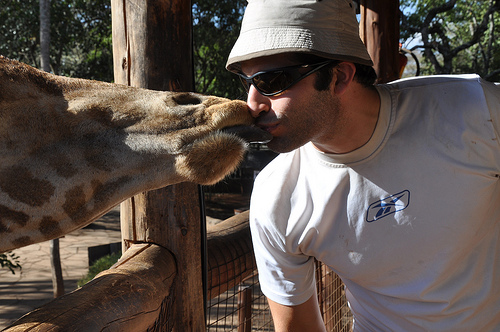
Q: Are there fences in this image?
A: Yes, there is a fence.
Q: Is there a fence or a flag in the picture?
A: Yes, there is a fence.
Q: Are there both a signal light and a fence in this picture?
A: No, there is a fence but no traffic lights.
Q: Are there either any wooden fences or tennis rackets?
A: Yes, there is a wood fence.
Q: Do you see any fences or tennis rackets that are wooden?
A: Yes, the fence is wooden.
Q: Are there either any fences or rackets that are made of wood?
A: Yes, the fence is made of wood.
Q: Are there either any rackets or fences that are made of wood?
A: Yes, the fence is made of wood.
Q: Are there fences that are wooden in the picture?
A: Yes, there is a wood fence.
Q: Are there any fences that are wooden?
A: Yes, there is a fence that is wooden.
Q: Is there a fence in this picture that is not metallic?
A: Yes, there is a wooden fence.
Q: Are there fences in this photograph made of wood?
A: Yes, there is a fence that is made of wood.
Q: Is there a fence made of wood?
A: Yes, there is a fence that is made of wood.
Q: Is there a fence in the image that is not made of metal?
A: Yes, there is a fence that is made of wood.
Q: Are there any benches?
A: No, there are no benches.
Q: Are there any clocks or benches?
A: No, there are no benches or clocks.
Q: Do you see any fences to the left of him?
A: Yes, there is a fence to the left of the man.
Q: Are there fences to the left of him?
A: Yes, there is a fence to the left of the man.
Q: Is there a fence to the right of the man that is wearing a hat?
A: No, the fence is to the left of the man.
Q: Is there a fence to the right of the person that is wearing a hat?
A: No, the fence is to the left of the man.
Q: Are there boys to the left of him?
A: No, there is a fence to the left of the man.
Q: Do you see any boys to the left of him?
A: No, there is a fence to the left of the man.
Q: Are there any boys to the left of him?
A: No, there is a fence to the left of the man.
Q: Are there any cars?
A: No, there are no cars.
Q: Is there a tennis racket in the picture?
A: No, there are no rackets.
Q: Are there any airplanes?
A: No, there are no airplanes.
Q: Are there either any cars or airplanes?
A: No, there are no airplanes or cars.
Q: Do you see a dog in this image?
A: No, there are no dogs.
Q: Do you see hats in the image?
A: Yes, there is a hat.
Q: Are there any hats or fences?
A: Yes, there is a hat.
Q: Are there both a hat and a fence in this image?
A: Yes, there are both a hat and a fence.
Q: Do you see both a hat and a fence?
A: Yes, there are both a hat and a fence.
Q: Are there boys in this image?
A: No, there are no boys.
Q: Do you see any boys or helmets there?
A: No, there are no boys or helmets.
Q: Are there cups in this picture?
A: Yes, there is a cup.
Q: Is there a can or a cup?
A: Yes, there is a cup.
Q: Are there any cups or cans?
A: Yes, there is a cup.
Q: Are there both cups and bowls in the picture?
A: No, there is a cup but no bowls.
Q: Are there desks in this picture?
A: No, there are no desks.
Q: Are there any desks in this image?
A: No, there are no desks.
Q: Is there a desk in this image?
A: No, there are no desks.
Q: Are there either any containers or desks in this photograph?
A: No, there are no desks or containers.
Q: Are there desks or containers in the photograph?
A: No, there are no desks or containers.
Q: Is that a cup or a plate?
A: That is a cup.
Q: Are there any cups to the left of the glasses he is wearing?
A: Yes, there is a cup to the left of the glasses.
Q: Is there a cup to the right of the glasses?
A: No, the cup is to the left of the glasses.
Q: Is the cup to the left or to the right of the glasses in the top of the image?
A: The cup is to the left of the glasses.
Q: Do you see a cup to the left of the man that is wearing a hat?
A: Yes, there is a cup to the left of the man.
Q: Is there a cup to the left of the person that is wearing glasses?
A: Yes, there is a cup to the left of the man.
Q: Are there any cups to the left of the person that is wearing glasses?
A: Yes, there is a cup to the left of the man.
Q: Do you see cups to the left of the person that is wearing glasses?
A: Yes, there is a cup to the left of the man.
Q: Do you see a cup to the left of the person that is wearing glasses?
A: Yes, there is a cup to the left of the man.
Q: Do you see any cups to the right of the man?
A: No, the cup is to the left of the man.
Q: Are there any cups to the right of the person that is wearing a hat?
A: No, the cup is to the left of the man.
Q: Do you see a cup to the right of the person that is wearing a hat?
A: No, the cup is to the left of the man.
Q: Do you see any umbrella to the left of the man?
A: No, there is a cup to the left of the man.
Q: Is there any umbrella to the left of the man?
A: No, there is a cup to the left of the man.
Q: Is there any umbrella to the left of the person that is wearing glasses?
A: No, there is a cup to the left of the man.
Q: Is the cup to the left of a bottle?
A: No, the cup is to the left of the man.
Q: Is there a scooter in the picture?
A: No, there are no scooters.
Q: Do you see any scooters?
A: No, there are no scooters.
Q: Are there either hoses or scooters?
A: No, there are no scooters or hoses.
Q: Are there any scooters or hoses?
A: No, there are no scooters or hoses.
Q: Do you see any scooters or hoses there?
A: No, there are no scooters or hoses.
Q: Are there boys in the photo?
A: No, there are no boys.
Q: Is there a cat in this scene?
A: No, there are no cats.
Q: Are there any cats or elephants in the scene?
A: No, there are no cats or elephants.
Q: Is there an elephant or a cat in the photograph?
A: No, there are no cats or elephants.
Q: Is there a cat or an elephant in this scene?
A: No, there are no cats or elephants.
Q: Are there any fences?
A: Yes, there is a fence.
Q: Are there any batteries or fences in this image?
A: Yes, there is a fence.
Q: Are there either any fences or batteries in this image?
A: Yes, there is a fence.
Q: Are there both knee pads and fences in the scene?
A: No, there is a fence but no knee pads.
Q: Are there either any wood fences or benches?
A: Yes, there is a wood fence.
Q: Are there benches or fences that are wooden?
A: Yes, the fence is wooden.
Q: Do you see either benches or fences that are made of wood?
A: Yes, the fence is made of wood.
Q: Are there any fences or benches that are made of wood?
A: Yes, the fence is made of wood.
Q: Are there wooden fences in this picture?
A: Yes, there is a wood fence.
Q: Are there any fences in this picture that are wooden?
A: Yes, there is a fence that is wooden.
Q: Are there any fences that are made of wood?
A: Yes, there is a fence that is made of wood.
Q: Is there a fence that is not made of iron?
A: Yes, there is a fence that is made of wood.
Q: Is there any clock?
A: No, there are no clocks.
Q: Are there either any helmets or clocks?
A: No, there are no clocks or helmets.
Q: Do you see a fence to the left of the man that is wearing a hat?
A: Yes, there is a fence to the left of the man.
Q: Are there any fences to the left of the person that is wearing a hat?
A: Yes, there is a fence to the left of the man.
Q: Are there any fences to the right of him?
A: No, the fence is to the left of the man.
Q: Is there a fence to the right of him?
A: No, the fence is to the left of the man.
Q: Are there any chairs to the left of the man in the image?
A: No, there is a fence to the left of the man.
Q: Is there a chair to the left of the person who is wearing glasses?
A: No, there is a fence to the left of the man.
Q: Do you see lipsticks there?
A: No, there are no lipsticks.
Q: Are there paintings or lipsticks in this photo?
A: No, there are no lipsticks or paintings.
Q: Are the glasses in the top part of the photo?
A: Yes, the glasses are in the top of the image.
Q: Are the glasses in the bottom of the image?
A: No, the glasses are in the top of the image.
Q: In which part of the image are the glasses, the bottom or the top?
A: The glasses are in the top of the image.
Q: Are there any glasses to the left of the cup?
A: No, the glasses are to the right of the cup.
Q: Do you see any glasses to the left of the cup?
A: No, the glasses are to the right of the cup.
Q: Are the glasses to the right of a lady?
A: No, the glasses are to the right of the cup.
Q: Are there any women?
A: No, there are no women.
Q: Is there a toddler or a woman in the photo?
A: No, there are no women or toddlers.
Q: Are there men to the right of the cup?
A: Yes, there is a man to the right of the cup.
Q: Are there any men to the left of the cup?
A: No, the man is to the right of the cup.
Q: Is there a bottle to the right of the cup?
A: No, there is a man to the right of the cup.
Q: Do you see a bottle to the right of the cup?
A: No, there is a man to the right of the cup.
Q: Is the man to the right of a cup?
A: Yes, the man is to the right of a cup.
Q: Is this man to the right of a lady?
A: No, the man is to the right of a cup.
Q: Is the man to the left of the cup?
A: No, the man is to the right of the cup.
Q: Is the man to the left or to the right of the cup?
A: The man is to the right of the cup.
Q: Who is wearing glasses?
A: The man is wearing glasses.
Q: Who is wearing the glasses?
A: The man is wearing glasses.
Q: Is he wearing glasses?
A: Yes, the man is wearing glasses.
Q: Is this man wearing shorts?
A: No, the man is wearing glasses.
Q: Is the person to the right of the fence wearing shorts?
A: No, the man is wearing glasses.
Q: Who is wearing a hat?
A: The man is wearing a hat.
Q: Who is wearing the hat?
A: The man is wearing a hat.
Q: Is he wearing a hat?
A: Yes, the man is wearing a hat.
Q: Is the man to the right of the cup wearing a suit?
A: No, the man is wearing a hat.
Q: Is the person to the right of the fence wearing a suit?
A: No, the man is wearing a hat.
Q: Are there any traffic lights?
A: No, there are no traffic lights.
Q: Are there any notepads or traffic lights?
A: No, there are no traffic lights or notepads.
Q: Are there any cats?
A: No, there are no cats.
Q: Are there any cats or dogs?
A: No, there are no cats or dogs.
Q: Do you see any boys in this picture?
A: No, there are no boys.